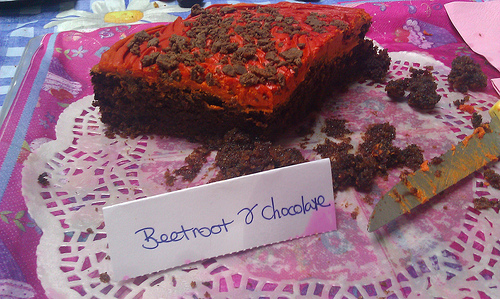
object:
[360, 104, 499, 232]
frosting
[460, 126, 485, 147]
crumbs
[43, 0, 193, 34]
daisy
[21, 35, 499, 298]
doyle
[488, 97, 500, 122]
handle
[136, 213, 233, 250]
beetroot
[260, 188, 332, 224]
chocolate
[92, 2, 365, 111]
orange frosting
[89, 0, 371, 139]
cake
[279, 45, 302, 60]
chunk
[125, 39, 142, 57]
chunk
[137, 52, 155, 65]
chunk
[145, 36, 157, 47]
chunk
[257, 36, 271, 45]
chunk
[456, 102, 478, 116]
crumbs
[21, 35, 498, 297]
doily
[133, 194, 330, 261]
blue inkprint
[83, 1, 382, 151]
chocolate cake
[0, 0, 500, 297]
tray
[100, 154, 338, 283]
label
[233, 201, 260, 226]
inkprint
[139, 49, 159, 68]
chocolate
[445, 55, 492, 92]
cupcake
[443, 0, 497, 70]
napkin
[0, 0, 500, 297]
table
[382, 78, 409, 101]
chunks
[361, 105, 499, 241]
knife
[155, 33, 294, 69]
bits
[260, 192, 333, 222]
inkprint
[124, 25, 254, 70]
topping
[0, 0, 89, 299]
tablecloth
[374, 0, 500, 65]
tablecloth